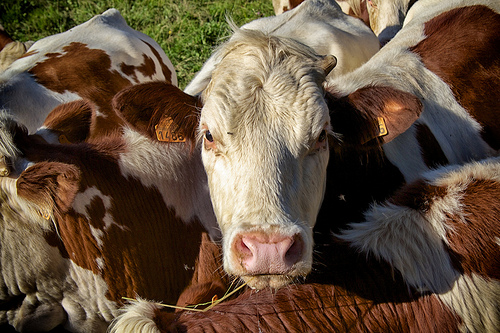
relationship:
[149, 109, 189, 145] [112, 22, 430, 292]
yellow tag on cow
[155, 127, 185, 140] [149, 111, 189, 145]
black numbers on yellow tag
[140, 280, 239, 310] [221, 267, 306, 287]
hay in cow's mouth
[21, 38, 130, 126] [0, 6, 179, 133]
skin belonging to cow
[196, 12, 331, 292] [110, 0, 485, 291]
fur belonging to cow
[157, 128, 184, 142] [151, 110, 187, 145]
writing printed on tag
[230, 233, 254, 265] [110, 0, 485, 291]
nostril belonging to cow